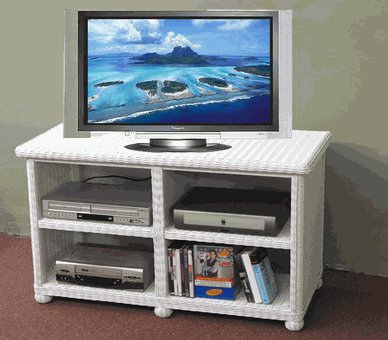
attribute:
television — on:
[60, 15, 282, 133]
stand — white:
[13, 120, 331, 330]